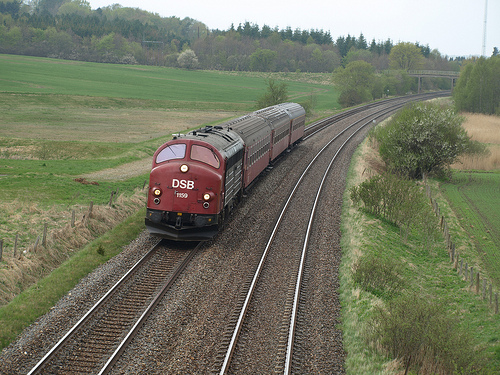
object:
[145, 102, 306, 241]
train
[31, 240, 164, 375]
track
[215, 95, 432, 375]
track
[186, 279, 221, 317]
pebbles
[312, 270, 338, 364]
pebbles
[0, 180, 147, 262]
fence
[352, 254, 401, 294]
bush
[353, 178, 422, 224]
bush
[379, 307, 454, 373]
bush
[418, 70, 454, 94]
overpass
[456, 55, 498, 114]
trees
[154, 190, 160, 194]
headlights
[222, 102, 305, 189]
cars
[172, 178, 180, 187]
letters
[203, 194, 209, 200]
light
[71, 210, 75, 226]
post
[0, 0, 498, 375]
background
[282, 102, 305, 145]
car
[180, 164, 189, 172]
headlight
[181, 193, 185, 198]
numbers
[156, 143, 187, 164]
window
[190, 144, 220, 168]
window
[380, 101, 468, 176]
tree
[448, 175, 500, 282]
crops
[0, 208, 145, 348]
grass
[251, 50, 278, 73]
trees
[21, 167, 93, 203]
grass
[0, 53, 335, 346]
field